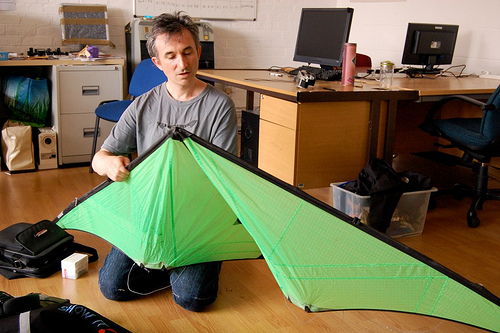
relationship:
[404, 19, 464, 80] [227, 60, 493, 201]
computer on desk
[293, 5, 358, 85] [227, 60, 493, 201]
computer on desk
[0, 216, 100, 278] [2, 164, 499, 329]
bag on floor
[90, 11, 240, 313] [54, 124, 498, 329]
man holding kite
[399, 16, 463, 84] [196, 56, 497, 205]
monitor on desk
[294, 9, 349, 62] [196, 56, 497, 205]
monitor on desk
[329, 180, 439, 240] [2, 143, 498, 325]
bin on floor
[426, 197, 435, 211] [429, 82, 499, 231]
wheels on chair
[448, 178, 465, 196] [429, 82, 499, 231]
wheels on chair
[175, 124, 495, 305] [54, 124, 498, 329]
black edge on kite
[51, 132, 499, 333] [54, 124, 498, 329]
black edge on kite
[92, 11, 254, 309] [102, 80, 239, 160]
man wearing shirt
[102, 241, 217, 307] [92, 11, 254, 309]
jeans on man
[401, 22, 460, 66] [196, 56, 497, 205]
monitor on desk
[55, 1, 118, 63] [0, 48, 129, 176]
monitor on desk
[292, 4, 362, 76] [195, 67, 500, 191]
monitor on desk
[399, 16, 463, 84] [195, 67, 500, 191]
monitor on desk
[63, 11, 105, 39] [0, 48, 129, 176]
monitor on desk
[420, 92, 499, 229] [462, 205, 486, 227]
chair with wheel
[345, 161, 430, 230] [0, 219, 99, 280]
jacket in bag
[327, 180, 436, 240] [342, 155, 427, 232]
bin full of item